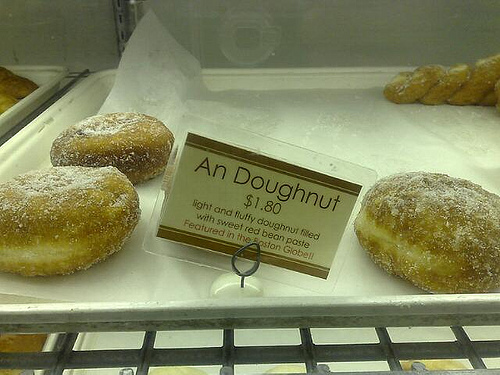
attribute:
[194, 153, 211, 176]
letter — BROWN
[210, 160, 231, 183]
letter — BROWN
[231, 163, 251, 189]
letter — BROWN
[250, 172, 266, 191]
letter — BROWN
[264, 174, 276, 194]
letter — BROWN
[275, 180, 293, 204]
letter — BROWN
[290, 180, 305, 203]
letter — BROWN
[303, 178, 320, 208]
letter — BROWN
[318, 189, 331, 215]
letter — BROWN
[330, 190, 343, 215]
letter — BROWN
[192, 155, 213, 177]
letter — BLACK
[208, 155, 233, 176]
letter — BLACK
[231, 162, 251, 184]
letter — BLACK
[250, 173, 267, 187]
letter — BLACK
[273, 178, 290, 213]
letter — black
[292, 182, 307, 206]
letter — black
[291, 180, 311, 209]
letter — black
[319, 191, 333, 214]
letter — black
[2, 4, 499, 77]
wall — white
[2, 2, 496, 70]
wall — clean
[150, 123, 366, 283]
tag — big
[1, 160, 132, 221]
sprinkles — white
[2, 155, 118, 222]
topping — white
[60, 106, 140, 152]
topping — white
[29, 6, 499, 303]
paper — polythene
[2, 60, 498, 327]
tray — white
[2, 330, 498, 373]
stand — metal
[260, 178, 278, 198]
letter — black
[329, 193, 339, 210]
letter — black